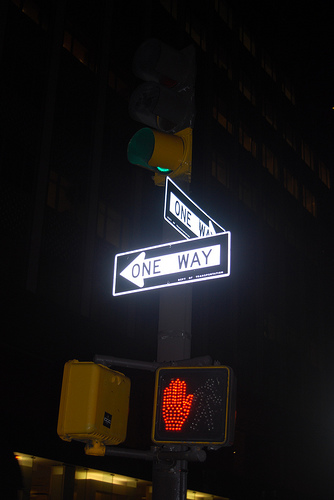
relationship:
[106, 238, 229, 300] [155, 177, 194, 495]
street signs on a pole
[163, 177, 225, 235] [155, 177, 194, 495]
street signs on a pole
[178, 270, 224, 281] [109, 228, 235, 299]
writing on sign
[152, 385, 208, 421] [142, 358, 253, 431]
hand on signal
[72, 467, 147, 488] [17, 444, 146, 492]
lights on building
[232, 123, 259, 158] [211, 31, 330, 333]
window on building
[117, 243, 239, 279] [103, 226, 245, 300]
arrow on sign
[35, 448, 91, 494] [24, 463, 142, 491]
window on building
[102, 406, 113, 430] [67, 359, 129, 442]
sticker on light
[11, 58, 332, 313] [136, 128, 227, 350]
building near pole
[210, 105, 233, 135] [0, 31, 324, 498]
window on building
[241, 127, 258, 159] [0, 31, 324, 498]
window on building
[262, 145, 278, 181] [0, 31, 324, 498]
window on building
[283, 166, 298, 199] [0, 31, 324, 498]
window on building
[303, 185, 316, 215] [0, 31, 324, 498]
window on building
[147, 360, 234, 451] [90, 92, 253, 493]
sign on pole